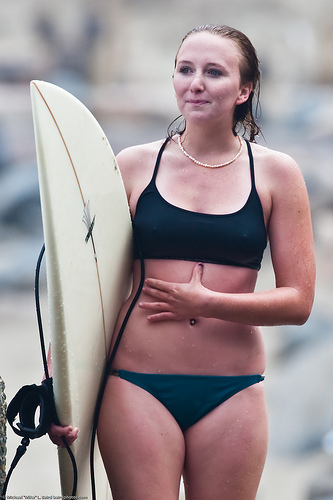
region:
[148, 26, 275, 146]
head of woman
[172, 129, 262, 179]
small necklace around face of woman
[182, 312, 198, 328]
pierced belly button of woman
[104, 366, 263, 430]
black bottom to bathing suit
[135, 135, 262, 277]
black top to bathing suit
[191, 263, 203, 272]
painted finger nail on hand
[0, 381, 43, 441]
black Velcro on end of leash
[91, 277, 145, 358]
liong black leash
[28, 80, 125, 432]
white surf board being held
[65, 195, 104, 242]
logo on bottom of board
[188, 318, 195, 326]
belly button ring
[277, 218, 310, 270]
the womens arm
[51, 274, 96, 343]
the surfboard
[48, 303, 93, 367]
water on the surfboard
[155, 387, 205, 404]
a bikini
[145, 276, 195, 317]
hand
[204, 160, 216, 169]
a necklace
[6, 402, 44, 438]
a black strap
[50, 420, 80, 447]
the women is holding the surfboard that is white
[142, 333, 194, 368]
womens stomach has water on it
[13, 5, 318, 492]
a woman holding a surfboard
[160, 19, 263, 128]
the head of a woman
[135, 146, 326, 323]
the arm of a woman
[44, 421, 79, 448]
the hand of a woman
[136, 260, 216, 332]
the hand of a woman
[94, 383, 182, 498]
the leg of a woman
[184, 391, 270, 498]
the leg of a woman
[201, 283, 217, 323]
the wrist of a woman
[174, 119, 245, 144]
the neck of a woman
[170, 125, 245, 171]
the girl is wearing a necklace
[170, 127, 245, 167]
the necklace is white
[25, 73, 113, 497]
she is wearing a surfboard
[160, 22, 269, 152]
her hair is wet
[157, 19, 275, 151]
her hair is dark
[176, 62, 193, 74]
she is wearing mascara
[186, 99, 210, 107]
her lips are pink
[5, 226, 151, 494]
the strap is black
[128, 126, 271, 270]
her bikini top is blue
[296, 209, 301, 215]
a freckle on her arm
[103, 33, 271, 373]
woman holding surf board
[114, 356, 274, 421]
teal bikini on woman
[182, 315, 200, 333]
belly button of surfer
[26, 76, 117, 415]
white board in surfer's arm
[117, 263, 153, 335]
black strap of board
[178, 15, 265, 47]
wet hair of surfer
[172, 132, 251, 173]
necklace on surfer's neck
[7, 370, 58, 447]
foot strap on board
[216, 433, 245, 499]
water drops on leg